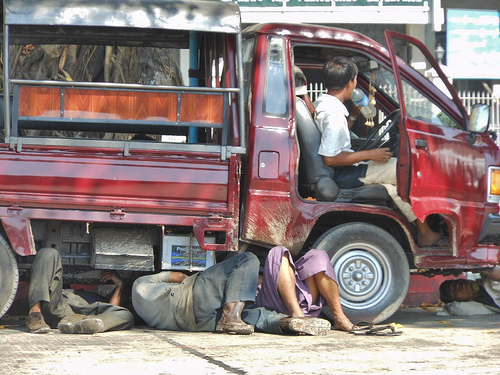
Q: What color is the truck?
A: Red.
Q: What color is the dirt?
A: Brown.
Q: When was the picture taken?
A: Daytime.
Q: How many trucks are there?
A: One.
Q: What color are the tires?
A: Black.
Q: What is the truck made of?
A: Metal.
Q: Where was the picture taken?
A: On the street.